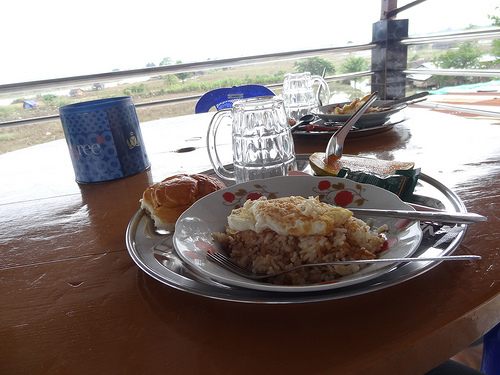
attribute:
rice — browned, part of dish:
[212, 219, 387, 287]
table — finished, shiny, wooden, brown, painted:
[5, 91, 495, 369]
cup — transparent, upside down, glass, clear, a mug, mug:
[205, 96, 297, 184]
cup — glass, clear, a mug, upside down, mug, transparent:
[282, 72, 328, 127]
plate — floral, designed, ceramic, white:
[171, 177, 423, 292]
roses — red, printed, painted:
[221, 183, 274, 207]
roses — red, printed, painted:
[316, 179, 366, 207]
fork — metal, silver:
[207, 250, 482, 279]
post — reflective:
[373, 19, 409, 102]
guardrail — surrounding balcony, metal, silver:
[4, 27, 496, 127]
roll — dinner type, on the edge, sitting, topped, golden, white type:
[140, 173, 227, 229]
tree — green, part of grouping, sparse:
[432, 39, 486, 71]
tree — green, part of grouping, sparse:
[342, 54, 370, 87]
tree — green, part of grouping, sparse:
[297, 55, 335, 79]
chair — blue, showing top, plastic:
[195, 84, 275, 113]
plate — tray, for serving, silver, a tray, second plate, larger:
[124, 152, 470, 304]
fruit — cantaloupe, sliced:
[308, 152, 422, 199]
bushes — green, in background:
[132, 71, 286, 100]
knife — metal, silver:
[342, 206, 489, 225]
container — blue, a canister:
[60, 96, 152, 184]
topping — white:
[227, 196, 352, 235]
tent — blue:
[20, 99, 37, 111]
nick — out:
[65, 278, 86, 289]